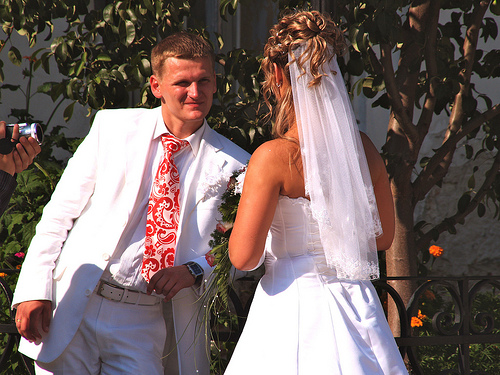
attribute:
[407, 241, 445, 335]
flowers — orange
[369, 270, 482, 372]
fence — black, cast iron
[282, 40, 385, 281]
veil — simple, white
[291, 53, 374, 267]
veil — white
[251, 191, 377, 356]
dress — white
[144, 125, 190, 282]
necktie — red, printed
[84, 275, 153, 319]
belt — white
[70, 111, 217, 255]
coat — white